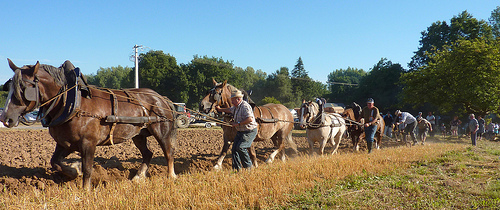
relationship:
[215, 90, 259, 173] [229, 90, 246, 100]
man wearing hat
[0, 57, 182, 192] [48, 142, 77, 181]
brown horse with raised foot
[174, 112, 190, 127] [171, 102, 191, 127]
tire on tractor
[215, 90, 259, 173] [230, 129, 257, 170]
man wearing a jeans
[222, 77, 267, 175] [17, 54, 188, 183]
man next to horses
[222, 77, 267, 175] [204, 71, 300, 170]
man next to horses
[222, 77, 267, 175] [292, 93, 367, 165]
man next to horses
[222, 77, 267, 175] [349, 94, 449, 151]
man next to horses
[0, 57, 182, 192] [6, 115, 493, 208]
brown horse are in a field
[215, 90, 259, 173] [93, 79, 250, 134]
man holds ropes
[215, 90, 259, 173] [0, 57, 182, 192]
man by brown horse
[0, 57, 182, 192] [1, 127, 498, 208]
brown horse in field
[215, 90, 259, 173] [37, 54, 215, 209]
man with horse